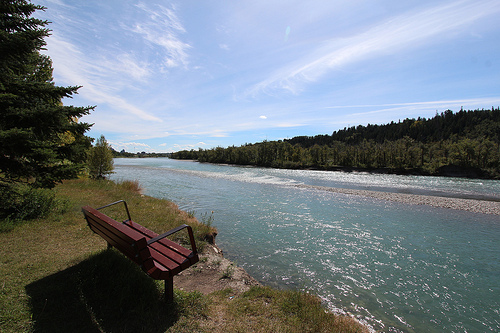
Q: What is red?
A: Bench.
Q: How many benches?
A: One.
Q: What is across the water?
A: Trees.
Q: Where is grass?
A: On ground.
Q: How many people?
A: None.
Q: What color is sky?
A: Blue.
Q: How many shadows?
A: One.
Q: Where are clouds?
A: In sky.